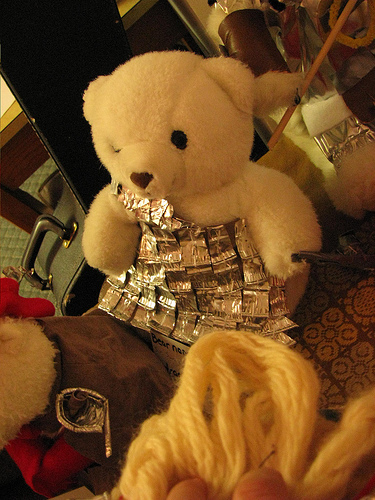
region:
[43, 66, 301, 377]
a teddy bear in a dress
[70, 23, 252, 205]
the head of a white teddy bear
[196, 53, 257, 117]
the ear of a white teddy bear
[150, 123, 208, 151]
the button eye of a white teddy bear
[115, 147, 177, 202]
the snout of a white teddy bear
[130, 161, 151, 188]
the nose of a white teddy bear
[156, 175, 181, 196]
the smile of a white teddy bear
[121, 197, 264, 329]
the dress of a white teddy bear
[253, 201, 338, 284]
the left arm of a white teddy bear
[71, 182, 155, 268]
the right arm of a white teddy bear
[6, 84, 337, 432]
two dolls are in the picture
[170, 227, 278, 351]
the clothing is silvery incolor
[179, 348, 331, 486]
thewool is lime white in color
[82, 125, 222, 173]
the eyes are black in oclor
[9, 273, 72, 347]
the doll is redin color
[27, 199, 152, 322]
the doll is next to a briefcase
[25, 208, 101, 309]
the briefcase is black in color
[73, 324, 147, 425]
the cloth is gray in color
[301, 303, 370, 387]
tye cloth is gray in color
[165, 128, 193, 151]
the eyes are black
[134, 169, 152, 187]
the nose is brown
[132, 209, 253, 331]
the foil is silver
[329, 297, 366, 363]
the ground is brown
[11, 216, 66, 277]
the handle is black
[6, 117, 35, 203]
the table is wooden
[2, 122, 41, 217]
the table is brown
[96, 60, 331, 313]
the teddybear is white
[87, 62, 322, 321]
the bear is fluffy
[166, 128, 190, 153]
Dark black eye of a teddy bear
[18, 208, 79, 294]
Handle of a bag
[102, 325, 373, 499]
Thick cream colored woolen strings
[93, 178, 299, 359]
Reflective material of teddy bear apron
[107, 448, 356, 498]
Fingers on the wool strings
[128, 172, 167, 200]
Snout on a teddy bear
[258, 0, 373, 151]
Thin long brown stick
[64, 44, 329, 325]
White colored teddy bear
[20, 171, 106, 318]
Dark green colored box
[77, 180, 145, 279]
Arm of a teddy bear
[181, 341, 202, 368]
part of a ribbon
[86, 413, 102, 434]
edge of a packet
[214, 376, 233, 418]
part of a ribbon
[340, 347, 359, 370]
part of a carpet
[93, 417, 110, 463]
edge of a paket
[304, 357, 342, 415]
part of a floor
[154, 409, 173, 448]
part of a ribbon